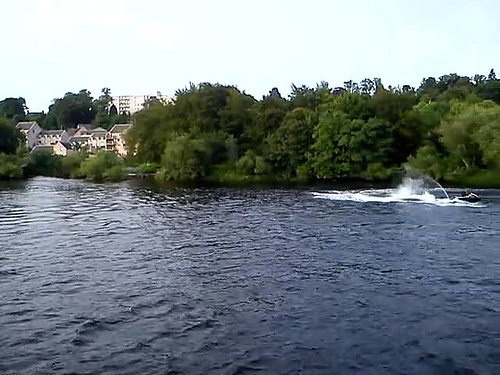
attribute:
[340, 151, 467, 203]
jetski — driven, alone, here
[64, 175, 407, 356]
water — splashing, spraying, here, green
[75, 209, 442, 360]
lake — here, blue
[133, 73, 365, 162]
trees — green, lined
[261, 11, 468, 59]
sky — blue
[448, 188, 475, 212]
person — riding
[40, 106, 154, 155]
buliding — tan, large, distant, white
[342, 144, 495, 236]
boat — riding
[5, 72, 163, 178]
bulidings — grouped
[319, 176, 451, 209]
foam — white